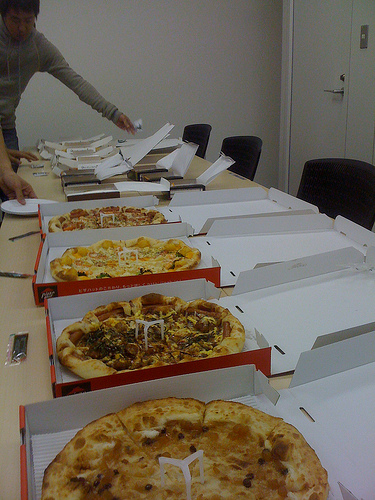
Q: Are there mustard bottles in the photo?
A: No, there are no mustard bottles.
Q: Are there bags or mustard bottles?
A: No, there are no mustard bottles or bags.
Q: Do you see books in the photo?
A: No, there are no books.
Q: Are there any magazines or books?
A: No, there are no books or magazines.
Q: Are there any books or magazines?
A: No, there are no books or magazines.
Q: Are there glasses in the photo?
A: No, there are no glasses.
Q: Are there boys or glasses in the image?
A: No, there are no glasses or boys.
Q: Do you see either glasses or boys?
A: No, there are no glasses or boys.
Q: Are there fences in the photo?
A: No, there are no fences.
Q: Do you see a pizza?
A: Yes, there is a pizza.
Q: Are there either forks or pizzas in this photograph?
A: Yes, there is a pizza.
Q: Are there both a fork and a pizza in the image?
A: No, there is a pizza but no forks.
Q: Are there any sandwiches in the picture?
A: No, there are no sandwiches.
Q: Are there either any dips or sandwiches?
A: No, there are no sandwiches or dips.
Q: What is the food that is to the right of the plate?
A: The food is a pizza.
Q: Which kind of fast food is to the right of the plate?
A: The food is a pizza.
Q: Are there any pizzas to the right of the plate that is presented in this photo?
A: Yes, there is a pizza to the right of the plate.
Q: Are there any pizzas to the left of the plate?
A: No, the pizza is to the right of the plate.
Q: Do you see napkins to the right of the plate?
A: No, there is a pizza to the right of the plate.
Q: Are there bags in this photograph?
A: No, there are no bags.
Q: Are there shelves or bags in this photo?
A: No, there are no bags or shelves.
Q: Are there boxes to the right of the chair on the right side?
A: No, the box is to the left of the chair.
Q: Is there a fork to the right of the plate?
A: No, there is a box to the right of the plate.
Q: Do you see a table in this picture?
A: Yes, there is a table.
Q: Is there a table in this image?
A: Yes, there is a table.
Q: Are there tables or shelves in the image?
A: Yes, there is a table.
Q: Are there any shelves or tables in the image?
A: Yes, there is a table.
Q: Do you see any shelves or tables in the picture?
A: Yes, there is a table.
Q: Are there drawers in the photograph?
A: No, there are no drawers.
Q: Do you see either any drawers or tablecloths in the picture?
A: No, there are no drawers or tablecloths.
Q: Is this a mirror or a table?
A: This is a table.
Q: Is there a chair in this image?
A: Yes, there is a chair.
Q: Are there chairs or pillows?
A: Yes, there is a chair.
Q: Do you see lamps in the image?
A: No, there are no lamps.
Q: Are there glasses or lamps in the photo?
A: No, there are no lamps or glasses.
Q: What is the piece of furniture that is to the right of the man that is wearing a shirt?
A: The piece of furniture is a chair.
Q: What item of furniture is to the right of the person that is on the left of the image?
A: The piece of furniture is a chair.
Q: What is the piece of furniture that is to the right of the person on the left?
A: The piece of furniture is a chair.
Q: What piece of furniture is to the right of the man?
A: The piece of furniture is a chair.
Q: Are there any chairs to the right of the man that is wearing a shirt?
A: Yes, there is a chair to the right of the man.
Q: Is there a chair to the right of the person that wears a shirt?
A: Yes, there is a chair to the right of the man.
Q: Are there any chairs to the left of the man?
A: No, the chair is to the right of the man.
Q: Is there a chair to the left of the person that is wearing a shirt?
A: No, the chair is to the right of the man.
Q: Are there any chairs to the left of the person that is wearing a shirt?
A: No, the chair is to the right of the man.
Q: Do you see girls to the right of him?
A: No, there is a chair to the right of the man.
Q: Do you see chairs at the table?
A: Yes, there is a chair at the table.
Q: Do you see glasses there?
A: No, there are no glasses.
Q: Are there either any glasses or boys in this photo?
A: No, there are no glasses or boys.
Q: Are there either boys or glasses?
A: No, there are no glasses or boys.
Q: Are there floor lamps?
A: No, there are no floor lamps.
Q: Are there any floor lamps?
A: No, there are no floor lamps.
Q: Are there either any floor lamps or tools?
A: No, there are no floor lamps or tools.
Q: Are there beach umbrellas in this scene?
A: No, there are no beach umbrellas.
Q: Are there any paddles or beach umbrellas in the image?
A: No, there are no beach umbrellas or paddles.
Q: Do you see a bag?
A: No, there are no bags.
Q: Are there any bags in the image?
A: No, there are no bags.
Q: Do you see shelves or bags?
A: No, there are no bags or shelves.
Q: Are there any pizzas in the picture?
A: Yes, there is a pizza.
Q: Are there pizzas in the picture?
A: Yes, there is a pizza.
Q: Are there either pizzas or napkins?
A: Yes, there is a pizza.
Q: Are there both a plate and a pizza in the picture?
A: Yes, there are both a pizza and a plate.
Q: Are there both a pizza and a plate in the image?
A: Yes, there are both a pizza and a plate.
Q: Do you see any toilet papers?
A: No, there are no toilet papers.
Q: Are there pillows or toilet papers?
A: No, there are no toilet papers or pillows.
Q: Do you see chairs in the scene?
A: Yes, there is a chair.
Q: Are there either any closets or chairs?
A: Yes, there is a chair.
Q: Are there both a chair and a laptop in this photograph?
A: No, there is a chair but no laptops.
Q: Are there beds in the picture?
A: No, there are no beds.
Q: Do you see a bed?
A: No, there are no beds.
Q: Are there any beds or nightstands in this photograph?
A: No, there are no beds or nightstands.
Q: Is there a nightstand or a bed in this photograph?
A: No, there are no beds or nightstands.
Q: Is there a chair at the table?
A: Yes, there is a chair at the table.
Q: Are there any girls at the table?
A: No, there is a chair at the table.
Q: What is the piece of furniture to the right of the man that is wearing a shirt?
A: The piece of furniture is a chair.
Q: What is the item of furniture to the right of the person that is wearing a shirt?
A: The piece of furniture is a chair.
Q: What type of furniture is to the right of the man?
A: The piece of furniture is a chair.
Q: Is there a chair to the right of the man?
A: Yes, there is a chair to the right of the man.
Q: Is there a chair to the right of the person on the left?
A: Yes, there is a chair to the right of the man.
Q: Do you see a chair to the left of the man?
A: No, the chair is to the right of the man.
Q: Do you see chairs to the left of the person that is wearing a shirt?
A: No, the chair is to the right of the man.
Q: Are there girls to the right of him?
A: No, there is a chair to the right of the man.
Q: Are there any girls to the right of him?
A: No, there is a chair to the right of the man.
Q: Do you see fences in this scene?
A: No, there are no fences.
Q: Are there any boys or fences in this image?
A: No, there are no fences or boys.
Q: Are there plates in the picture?
A: Yes, there is a plate.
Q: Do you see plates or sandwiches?
A: Yes, there is a plate.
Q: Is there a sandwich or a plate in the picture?
A: Yes, there is a plate.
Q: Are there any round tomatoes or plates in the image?
A: Yes, there is a round plate.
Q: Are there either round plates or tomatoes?
A: Yes, there is a round plate.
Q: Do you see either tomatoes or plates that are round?
A: Yes, the plate is round.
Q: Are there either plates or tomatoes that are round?
A: Yes, the plate is round.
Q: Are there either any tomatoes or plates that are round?
A: Yes, the plate is round.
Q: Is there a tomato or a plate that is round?
A: Yes, the plate is round.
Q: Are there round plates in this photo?
A: Yes, there is a round plate.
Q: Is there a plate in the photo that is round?
A: Yes, there is a plate that is round.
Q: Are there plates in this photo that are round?
A: Yes, there is a plate that is round.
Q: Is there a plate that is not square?
A: Yes, there is a round plate.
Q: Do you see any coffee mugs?
A: No, there are no coffee mugs.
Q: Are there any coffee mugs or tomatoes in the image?
A: No, there are no coffee mugs or tomatoes.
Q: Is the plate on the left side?
A: Yes, the plate is on the left of the image.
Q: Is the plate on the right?
A: No, the plate is on the left of the image.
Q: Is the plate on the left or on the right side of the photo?
A: The plate is on the left of the image.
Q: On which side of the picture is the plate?
A: The plate is on the left of the image.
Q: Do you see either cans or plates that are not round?
A: No, there is a plate but it is round.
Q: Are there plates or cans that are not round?
A: No, there is a plate but it is round.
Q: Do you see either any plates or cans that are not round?
A: No, there is a plate but it is round.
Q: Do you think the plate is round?
A: Yes, the plate is round.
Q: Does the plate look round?
A: Yes, the plate is round.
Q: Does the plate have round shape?
A: Yes, the plate is round.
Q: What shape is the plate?
A: The plate is round.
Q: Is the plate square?
A: No, the plate is round.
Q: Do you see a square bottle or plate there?
A: No, there is a plate but it is round.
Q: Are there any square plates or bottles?
A: No, there is a plate but it is round.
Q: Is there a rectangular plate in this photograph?
A: No, there is a plate but it is round.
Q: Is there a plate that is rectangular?
A: No, there is a plate but it is round.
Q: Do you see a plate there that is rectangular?
A: No, there is a plate but it is round.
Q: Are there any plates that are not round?
A: No, there is a plate but it is round.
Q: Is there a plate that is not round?
A: No, there is a plate but it is round.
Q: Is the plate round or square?
A: The plate is round.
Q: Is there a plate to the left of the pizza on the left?
A: Yes, there is a plate to the left of the pizza.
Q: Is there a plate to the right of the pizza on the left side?
A: No, the plate is to the left of the pizza.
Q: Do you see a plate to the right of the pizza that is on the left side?
A: No, the plate is to the left of the pizza.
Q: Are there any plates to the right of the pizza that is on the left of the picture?
A: No, the plate is to the left of the pizza.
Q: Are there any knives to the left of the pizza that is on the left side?
A: No, there is a plate to the left of the pizza.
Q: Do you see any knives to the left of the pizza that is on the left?
A: No, there is a plate to the left of the pizza.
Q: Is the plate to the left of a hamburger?
A: No, the plate is to the left of the pizza.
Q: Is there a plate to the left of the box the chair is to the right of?
A: Yes, there is a plate to the left of the box.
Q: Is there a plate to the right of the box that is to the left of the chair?
A: No, the plate is to the left of the box.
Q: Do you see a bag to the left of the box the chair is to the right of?
A: No, there is a plate to the left of the box.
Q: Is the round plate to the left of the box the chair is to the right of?
A: Yes, the plate is to the left of the box.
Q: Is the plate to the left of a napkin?
A: No, the plate is to the left of the box.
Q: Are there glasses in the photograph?
A: No, there are no glasses.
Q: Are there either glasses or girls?
A: No, there are no glasses or girls.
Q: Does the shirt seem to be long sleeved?
A: Yes, the shirt is long sleeved.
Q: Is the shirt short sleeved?
A: No, the shirt is long sleeved.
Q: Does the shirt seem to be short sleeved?
A: No, the shirt is long sleeved.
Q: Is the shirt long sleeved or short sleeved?
A: The shirt is long sleeved.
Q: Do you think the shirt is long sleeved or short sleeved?
A: The shirt is long sleeved.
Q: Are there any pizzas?
A: Yes, there is a pizza.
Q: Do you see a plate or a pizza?
A: Yes, there is a pizza.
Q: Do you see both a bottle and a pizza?
A: No, there is a pizza but no bottles.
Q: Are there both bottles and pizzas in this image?
A: No, there is a pizza but no bottles.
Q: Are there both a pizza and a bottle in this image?
A: No, there is a pizza but no bottles.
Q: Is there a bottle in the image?
A: No, there are no bottles.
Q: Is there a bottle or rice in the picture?
A: No, there are no bottles or rice.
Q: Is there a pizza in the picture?
A: Yes, there is a pizza.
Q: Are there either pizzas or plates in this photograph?
A: Yes, there is a pizza.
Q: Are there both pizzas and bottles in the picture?
A: No, there is a pizza but no bottles.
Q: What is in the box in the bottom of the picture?
A: The pizza is in the box.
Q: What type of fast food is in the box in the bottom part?
A: The food is a pizza.